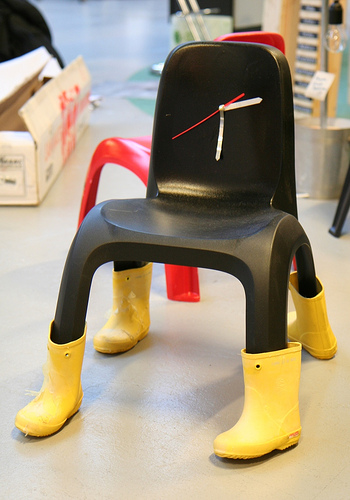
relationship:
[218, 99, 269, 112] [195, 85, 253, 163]
hand on clock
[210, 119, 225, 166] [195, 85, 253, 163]
hand on clock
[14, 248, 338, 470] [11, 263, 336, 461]
legs covered with boots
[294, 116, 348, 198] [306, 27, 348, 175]
basket by wall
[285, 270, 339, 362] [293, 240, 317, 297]
boot on leg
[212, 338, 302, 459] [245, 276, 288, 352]
boot on leg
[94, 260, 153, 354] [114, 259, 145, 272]
boot on leg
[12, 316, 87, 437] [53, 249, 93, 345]
boot on leg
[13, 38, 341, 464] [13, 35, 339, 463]
chair behind chair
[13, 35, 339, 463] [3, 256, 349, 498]
chair on floor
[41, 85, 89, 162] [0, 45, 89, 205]
label on box